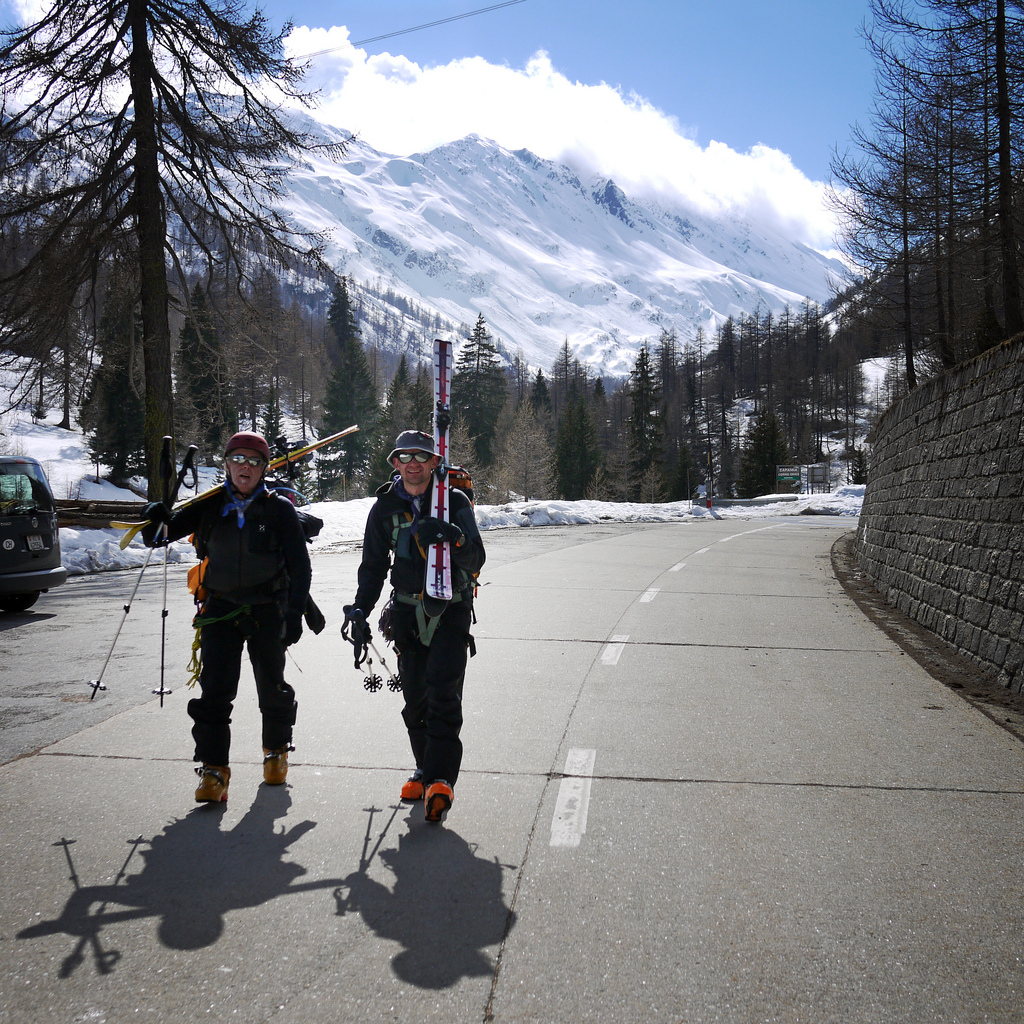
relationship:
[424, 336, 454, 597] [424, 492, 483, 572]
ski in arm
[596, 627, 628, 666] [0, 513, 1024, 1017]
stripe on street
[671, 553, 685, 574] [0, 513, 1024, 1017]
stripe on street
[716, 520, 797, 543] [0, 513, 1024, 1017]
stripe on street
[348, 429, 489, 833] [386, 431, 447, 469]
man wearing hat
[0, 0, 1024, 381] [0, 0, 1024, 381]
clouds in clouds